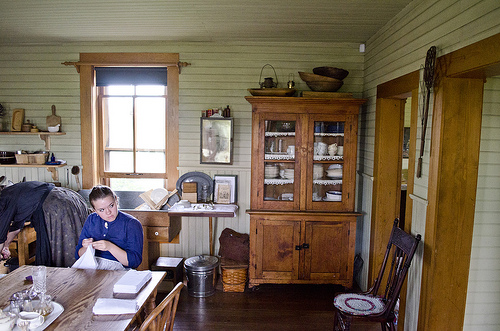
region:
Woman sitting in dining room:
[76, 182, 143, 268]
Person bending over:
[0, 179, 87, 267]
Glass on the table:
[31, 264, 48, 292]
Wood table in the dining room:
[1, 263, 164, 328]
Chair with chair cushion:
[332, 216, 422, 329]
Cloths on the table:
[92, 265, 152, 312]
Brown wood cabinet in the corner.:
[243, 92, 364, 289]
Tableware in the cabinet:
[264, 119, 344, 201]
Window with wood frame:
[77, 51, 177, 188]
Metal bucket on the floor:
[185, 251, 218, 297]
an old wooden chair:
[330, 216, 420, 327]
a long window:
[93, 69, 168, 195]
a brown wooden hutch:
[243, 91, 365, 288]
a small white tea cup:
[15, 308, 42, 326]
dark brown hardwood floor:
[160, 280, 345, 328]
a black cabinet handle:
[200, 115, 236, 163]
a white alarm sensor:
[355, 41, 365, 51]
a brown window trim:
[61, 48, 186, 188]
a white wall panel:
[473, 208, 498, 223]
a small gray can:
[182, 255, 219, 298]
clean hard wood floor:
[216, 292, 306, 316]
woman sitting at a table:
[80, 186, 139, 261]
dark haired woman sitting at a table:
[58, 165, 140, 258]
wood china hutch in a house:
[235, 70, 357, 277]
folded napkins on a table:
[94, 257, 159, 303]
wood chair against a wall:
[296, 227, 429, 327]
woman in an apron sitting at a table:
[71, 175, 131, 274]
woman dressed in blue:
[52, 168, 142, 263]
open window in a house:
[68, 53, 180, 183]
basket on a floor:
[216, 231, 263, 288]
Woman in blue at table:
[69, 181, 156, 277]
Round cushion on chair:
[330, 284, 397, 321]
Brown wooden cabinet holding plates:
[235, 73, 362, 290]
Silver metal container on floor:
[183, 249, 224, 308]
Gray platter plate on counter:
[171, 171, 217, 202]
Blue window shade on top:
[99, 65, 172, 95]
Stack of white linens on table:
[107, 266, 154, 304]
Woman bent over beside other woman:
[1, 168, 146, 280]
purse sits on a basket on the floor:
[211, 223, 259, 299]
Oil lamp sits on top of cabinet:
[250, 61, 298, 101]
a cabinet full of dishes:
[235, 91, 372, 289]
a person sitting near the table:
[76, 182, 143, 269]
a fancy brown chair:
[325, 227, 432, 329]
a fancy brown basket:
[242, 58, 293, 98]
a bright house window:
[89, 55, 183, 187]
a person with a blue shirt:
[73, 177, 148, 269]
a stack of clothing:
[15, 186, 85, 259]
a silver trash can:
[179, 251, 221, 302]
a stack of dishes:
[0, 281, 65, 329]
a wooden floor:
[216, 298, 323, 326]